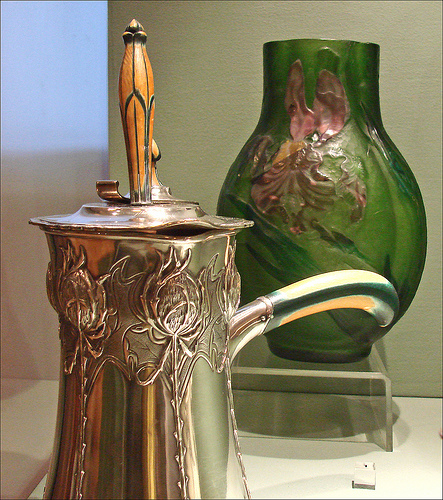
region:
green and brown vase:
[213, 31, 433, 372]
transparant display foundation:
[204, 321, 405, 461]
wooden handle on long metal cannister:
[115, 14, 177, 208]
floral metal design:
[56, 247, 215, 498]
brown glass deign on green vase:
[248, 60, 375, 242]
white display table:
[4, 369, 442, 496]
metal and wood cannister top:
[24, 12, 258, 242]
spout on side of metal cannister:
[230, 256, 412, 365]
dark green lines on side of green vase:
[221, 192, 327, 288]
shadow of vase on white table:
[233, 383, 411, 464]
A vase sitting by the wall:
[197, 23, 437, 344]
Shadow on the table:
[244, 392, 385, 462]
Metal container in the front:
[15, 178, 257, 490]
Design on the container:
[56, 258, 233, 387]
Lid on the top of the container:
[41, 150, 271, 267]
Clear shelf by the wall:
[240, 348, 431, 449]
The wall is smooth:
[410, 324, 435, 429]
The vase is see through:
[256, 101, 399, 256]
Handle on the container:
[233, 245, 431, 381]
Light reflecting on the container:
[107, 365, 216, 487]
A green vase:
[228, 32, 432, 355]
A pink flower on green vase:
[283, 48, 365, 157]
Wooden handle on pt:
[116, 20, 163, 194]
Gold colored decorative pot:
[33, 200, 250, 467]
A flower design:
[134, 259, 213, 491]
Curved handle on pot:
[238, 269, 410, 343]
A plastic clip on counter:
[342, 451, 388, 493]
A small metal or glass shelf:
[257, 356, 417, 463]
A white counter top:
[274, 445, 334, 498]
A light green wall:
[180, 40, 228, 129]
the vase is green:
[226, 11, 392, 406]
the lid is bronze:
[50, 164, 259, 289]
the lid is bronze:
[21, 193, 243, 266]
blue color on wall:
[31, 59, 84, 106]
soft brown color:
[16, 315, 50, 358]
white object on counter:
[343, 459, 385, 490]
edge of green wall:
[390, 383, 434, 412]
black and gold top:
[116, 12, 169, 41]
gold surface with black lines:
[107, 54, 168, 148]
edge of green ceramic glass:
[227, 21, 376, 66]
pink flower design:
[264, 52, 364, 227]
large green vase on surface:
[254, 32, 431, 321]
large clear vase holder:
[266, 357, 410, 431]